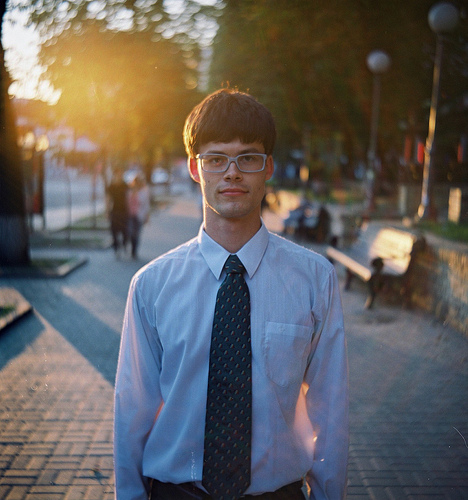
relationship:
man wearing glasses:
[114, 86, 354, 500] [188, 146, 273, 182]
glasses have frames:
[188, 146, 273, 182] [195, 150, 270, 174]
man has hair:
[114, 86, 354, 500] [181, 87, 278, 159]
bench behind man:
[330, 226, 422, 313] [114, 86, 354, 500]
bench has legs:
[330, 226, 422, 313] [327, 253, 415, 313]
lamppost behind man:
[365, 32, 442, 211] [114, 86, 354, 500]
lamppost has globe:
[365, 32, 442, 211] [366, 48, 395, 78]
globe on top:
[366, 48, 395, 78] [362, 7, 452, 83]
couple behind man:
[105, 170, 154, 258] [114, 86, 354, 500]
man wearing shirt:
[114, 86, 354, 500] [106, 228, 351, 454]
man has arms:
[114, 86, 354, 500] [306, 254, 351, 494]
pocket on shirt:
[260, 320, 315, 389] [106, 228, 351, 454]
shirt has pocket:
[106, 228, 351, 454] [260, 320, 315, 389]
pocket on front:
[260, 320, 315, 389] [132, 215, 348, 386]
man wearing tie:
[114, 86, 354, 500] [203, 258, 256, 500]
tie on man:
[203, 258, 256, 500] [114, 86, 354, 500]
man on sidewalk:
[114, 86, 354, 500] [21, 263, 116, 488]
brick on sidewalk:
[23, 387, 94, 426] [21, 263, 116, 488]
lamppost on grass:
[365, 32, 442, 211] [417, 211, 466, 237]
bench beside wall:
[330, 226, 422, 313] [403, 245, 467, 326]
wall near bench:
[403, 245, 467, 326] [330, 226, 422, 313]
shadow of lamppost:
[12, 257, 132, 376] [1, 74, 35, 275]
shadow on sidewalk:
[12, 257, 132, 376] [21, 263, 116, 488]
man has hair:
[114, 86, 354, 500] [184, 91, 279, 149]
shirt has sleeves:
[106, 228, 351, 454] [116, 275, 160, 486]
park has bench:
[266, 40, 465, 250] [330, 226, 422, 313]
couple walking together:
[105, 170, 154, 258] [102, 166, 153, 257]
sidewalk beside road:
[21, 263, 116, 488] [42, 176, 101, 209]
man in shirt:
[114, 86, 354, 500] [106, 228, 351, 454]